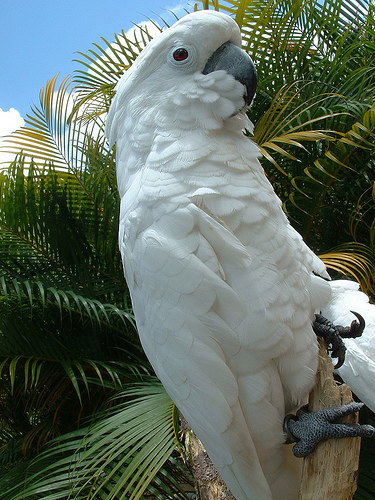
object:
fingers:
[320, 397, 363, 420]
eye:
[170, 45, 191, 66]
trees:
[4, 0, 374, 497]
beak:
[201, 39, 260, 106]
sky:
[0, 0, 375, 173]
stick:
[283, 324, 372, 500]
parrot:
[102, 4, 375, 500]